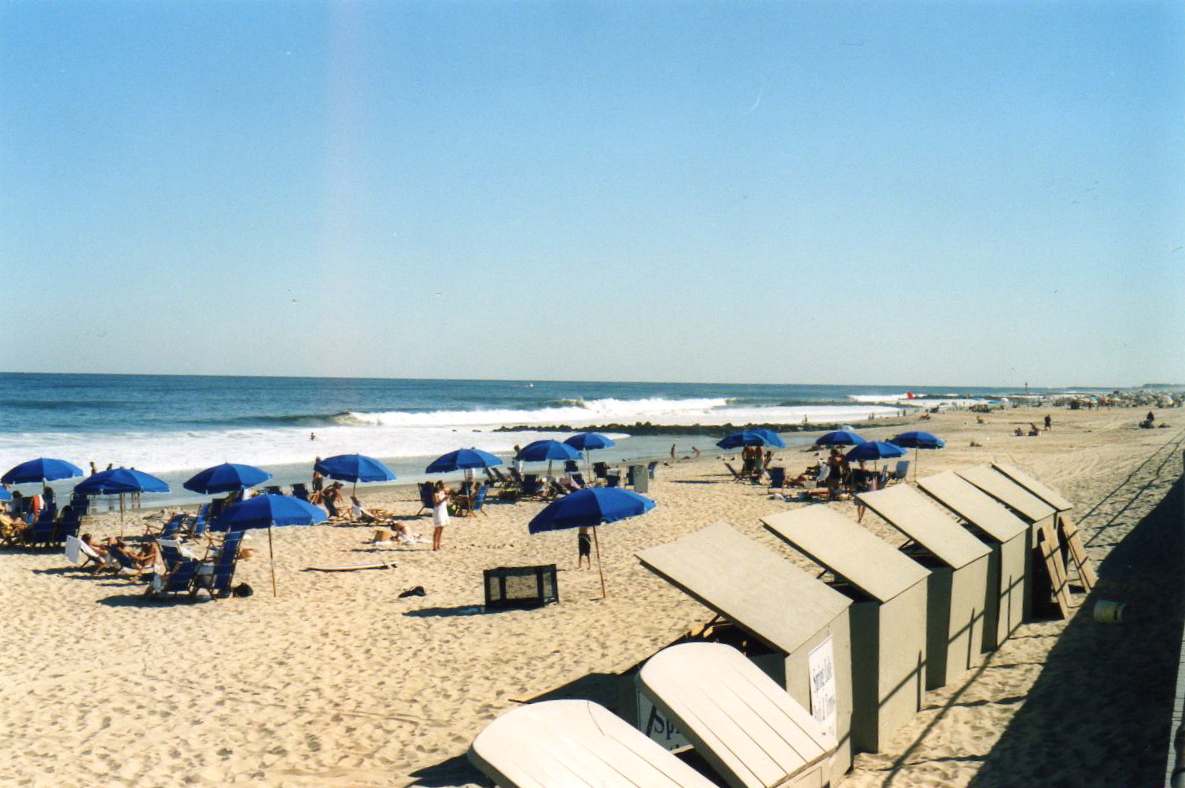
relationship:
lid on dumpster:
[637, 514, 858, 654] [635, 514, 859, 748]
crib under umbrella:
[482, 557, 566, 606] [527, 475, 649, 589]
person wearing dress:
[433, 480, 451, 551] [426, 496, 449, 526]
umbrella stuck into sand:
[529, 477, 658, 595] [1, 410, 1183, 784]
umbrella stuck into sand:
[530, 487, 656, 599] [1, 410, 1183, 784]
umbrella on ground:
[530, 487, 656, 599] [8, 392, 1145, 781]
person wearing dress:
[417, 476, 460, 553] [424, 502, 460, 540]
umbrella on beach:
[530, 487, 656, 599] [1, 394, 1132, 783]